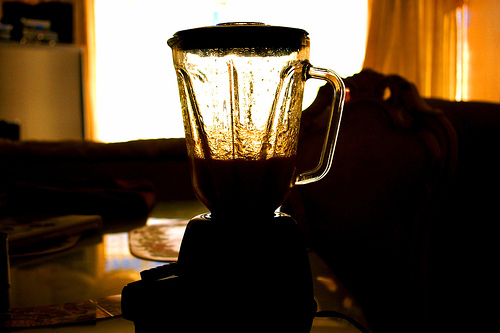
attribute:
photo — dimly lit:
[9, 10, 484, 314]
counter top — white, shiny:
[72, 193, 165, 315]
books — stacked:
[3, 8, 73, 45]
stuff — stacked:
[127, 218, 196, 260]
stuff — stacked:
[91, 291, 123, 320]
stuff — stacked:
[3, 297, 96, 331]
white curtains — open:
[360, 0, 497, 102]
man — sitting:
[301, 65, 463, 277]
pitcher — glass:
[162, 14, 346, 211]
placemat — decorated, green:
[126, 220, 188, 264]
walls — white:
[6, 8, 86, 135]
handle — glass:
[300, 69, 352, 191]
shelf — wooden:
[12, 9, 82, 59]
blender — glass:
[115, 19, 350, 330]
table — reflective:
[5, 200, 360, 331]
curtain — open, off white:
[463, 0, 500, 104]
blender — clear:
[165, 18, 347, 220]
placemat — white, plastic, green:
[108, 122, 312, 304]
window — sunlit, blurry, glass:
[94, 3, 368, 139]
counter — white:
[17, 253, 126, 330]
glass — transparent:
[75, 6, 382, 148]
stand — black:
[116, 213, 324, 326]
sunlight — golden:
[1, 2, 499, 330]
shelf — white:
[0, 43, 86, 140]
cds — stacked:
[0, 0, 74, 44]